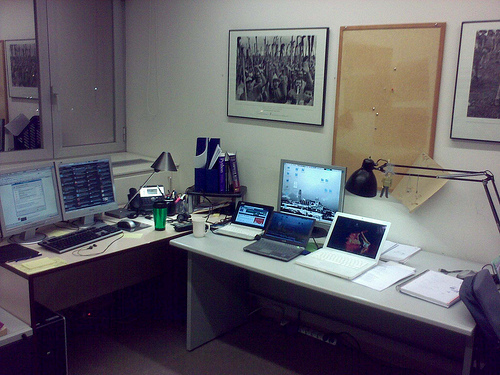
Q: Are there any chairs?
A: No, there are no chairs.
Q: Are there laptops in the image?
A: Yes, there is a laptop.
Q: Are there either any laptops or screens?
A: Yes, there is a laptop.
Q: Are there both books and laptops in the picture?
A: Yes, there are both a laptop and a book.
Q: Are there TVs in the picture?
A: No, there are no tvs.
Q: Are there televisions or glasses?
A: No, there are no televisions or glasses.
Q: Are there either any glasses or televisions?
A: No, there are no televisions or glasses.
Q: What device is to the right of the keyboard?
A: The device is a laptop.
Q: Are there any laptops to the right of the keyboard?
A: Yes, there is a laptop to the right of the keyboard.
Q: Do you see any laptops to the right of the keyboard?
A: Yes, there is a laptop to the right of the keyboard.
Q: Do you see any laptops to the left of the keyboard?
A: No, the laptop is to the right of the keyboard.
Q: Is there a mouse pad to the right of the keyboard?
A: No, there is a laptop to the right of the keyboard.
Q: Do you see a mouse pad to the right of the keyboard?
A: No, there is a laptop to the right of the keyboard.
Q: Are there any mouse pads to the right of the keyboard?
A: No, there is a laptop to the right of the keyboard.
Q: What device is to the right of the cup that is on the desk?
A: The device is a laptop.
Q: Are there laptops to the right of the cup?
A: Yes, there is a laptop to the right of the cup.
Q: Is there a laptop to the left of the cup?
A: No, the laptop is to the right of the cup.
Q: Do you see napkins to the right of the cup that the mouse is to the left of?
A: No, there is a laptop to the right of the cup.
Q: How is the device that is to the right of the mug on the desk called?
A: The device is a laptop.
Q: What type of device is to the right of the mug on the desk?
A: The device is a laptop.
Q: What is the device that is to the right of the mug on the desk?
A: The device is a laptop.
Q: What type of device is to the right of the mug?
A: The device is a laptop.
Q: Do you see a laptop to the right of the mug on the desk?
A: Yes, there is a laptop to the right of the mug.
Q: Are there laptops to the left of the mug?
A: No, the laptop is to the right of the mug.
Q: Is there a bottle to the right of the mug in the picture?
A: No, there is a laptop to the right of the mug.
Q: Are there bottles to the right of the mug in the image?
A: No, there is a laptop to the right of the mug.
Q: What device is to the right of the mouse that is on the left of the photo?
A: The device is a laptop.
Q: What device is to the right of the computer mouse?
A: The device is a laptop.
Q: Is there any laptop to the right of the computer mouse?
A: Yes, there is a laptop to the right of the computer mouse.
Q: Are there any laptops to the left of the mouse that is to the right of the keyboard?
A: No, the laptop is to the right of the mouse.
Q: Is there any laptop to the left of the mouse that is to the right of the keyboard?
A: No, the laptop is to the right of the mouse.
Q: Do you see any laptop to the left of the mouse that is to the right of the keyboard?
A: No, the laptop is to the right of the mouse.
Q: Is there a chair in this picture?
A: No, there are no chairs.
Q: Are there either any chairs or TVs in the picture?
A: No, there are no chairs or tvs.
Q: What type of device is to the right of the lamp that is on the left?
A: The device is a computer monitor.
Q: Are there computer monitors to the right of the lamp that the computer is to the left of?
A: Yes, there is a computer monitor to the right of the lamp.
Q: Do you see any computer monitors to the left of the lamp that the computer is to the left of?
A: No, the computer monitor is to the right of the lamp.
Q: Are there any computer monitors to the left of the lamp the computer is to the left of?
A: No, the computer monitor is to the right of the lamp.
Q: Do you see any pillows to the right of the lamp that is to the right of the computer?
A: No, there is a computer monitor to the right of the lamp.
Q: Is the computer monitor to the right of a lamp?
A: Yes, the computer monitor is to the right of a lamp.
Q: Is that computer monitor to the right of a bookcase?
A: No, the computer monitor is to the right of a lamp.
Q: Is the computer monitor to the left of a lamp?
A: No, the computer monitor is to the right of a lamp.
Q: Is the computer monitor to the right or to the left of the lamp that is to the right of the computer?
A: The computer monitor is to the right of the lamp.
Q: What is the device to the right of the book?
A: The device is a computer monitor.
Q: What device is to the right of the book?
A: The device is a computer monitor.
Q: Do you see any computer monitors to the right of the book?
A: Yes, there is a computer monitor to the right of the book.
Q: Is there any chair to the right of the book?
A: No, there is a computer monitor to the right of the book.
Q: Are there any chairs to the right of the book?
A: No, there is a computer monitor to the right of the book.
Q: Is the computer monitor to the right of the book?
A: Yes, the computer monitor is to the right of the book.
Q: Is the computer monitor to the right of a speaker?
A: No, the computer monitor is to the right of the book.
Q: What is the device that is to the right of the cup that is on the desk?
A: The device is a computer monitor.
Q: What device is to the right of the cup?
A: The device is a computer monitor.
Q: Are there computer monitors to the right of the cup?
A: Yes, there is a computer monitor to the right of the cup.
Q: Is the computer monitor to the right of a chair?
A: No, the computer monitor is to the right of the cup.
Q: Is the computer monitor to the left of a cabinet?
A: No, the computer monitor is to the left of a lamp.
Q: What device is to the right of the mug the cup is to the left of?
A: The device is a computer monitor.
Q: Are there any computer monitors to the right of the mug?
A: Yes, there is a computer monitor to the right of the mug.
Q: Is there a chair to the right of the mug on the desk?
A: No, there is a computer monitor to the right of the mug.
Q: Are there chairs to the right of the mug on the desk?
A: No, there is a computer monitor to the right of the mug.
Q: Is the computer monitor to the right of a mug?
A: Yes, the computer monitor is to the right of a mug.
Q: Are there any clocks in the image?
A: No, there are no clocks.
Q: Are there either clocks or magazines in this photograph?
A: No, there are no clocks or magazines.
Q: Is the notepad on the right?
A: Yes, the notepad is on the right of the image.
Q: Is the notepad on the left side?
A: No, the notepad is on the right of the image.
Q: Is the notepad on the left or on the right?
A: The notepad is on the right of the image.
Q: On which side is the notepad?
A: The notepad is on the right of the image.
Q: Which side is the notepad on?
A: The notepad is on the right of the image.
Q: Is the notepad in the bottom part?
A: Yes, the notepad is in the bottom of the image.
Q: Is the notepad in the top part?
A: No, the notepad is in the bottom of the image.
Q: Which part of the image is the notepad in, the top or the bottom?
A: The notepad is in the bottom of the image.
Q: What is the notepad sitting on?
A: The notepad is sitting on the desk.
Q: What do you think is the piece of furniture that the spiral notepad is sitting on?
A: The piece of furniture is a desk.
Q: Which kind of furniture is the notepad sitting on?
A: The notepad is sitting on the desk.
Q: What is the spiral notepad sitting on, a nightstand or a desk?
A: The notepad is sitting on a desk.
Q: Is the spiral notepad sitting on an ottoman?
A: No, the notepad is sitting on the desk.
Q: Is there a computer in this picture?
A: Yes, there is a computer.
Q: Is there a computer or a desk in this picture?
A: Yes, there is a computer.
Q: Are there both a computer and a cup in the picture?
A: Yes, there are both a computer and a cup.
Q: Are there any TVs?
A: No, there are no tvs.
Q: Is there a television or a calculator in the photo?
A: No, there are no televisions or calculators.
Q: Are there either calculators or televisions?
A: No, there are no televisions or calculators.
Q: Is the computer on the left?
A: Yes, the computer is on the left of the image.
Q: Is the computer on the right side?
A: No, the computer is on the left of the image.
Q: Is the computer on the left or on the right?
A: The computer is on the left of the image.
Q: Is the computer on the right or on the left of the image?
A: The computer is on the left of the image.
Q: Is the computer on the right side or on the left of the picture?
A: The computer is on the left of the image.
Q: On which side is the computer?
A: The computer is on the left of the image.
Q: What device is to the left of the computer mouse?
A: The device is a computer.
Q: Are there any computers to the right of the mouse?
A: No, the computer is to the left of the mouse.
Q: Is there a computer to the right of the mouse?
A: No, the computer is to the left of the mouse.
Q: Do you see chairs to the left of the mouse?
A: No, there is a computer to the left of the mouse.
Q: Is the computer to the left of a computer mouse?
A: Yes, the computer is to the left of a computer mouse.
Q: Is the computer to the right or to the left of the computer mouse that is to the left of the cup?
A: The computer is to the left of the computer mouse.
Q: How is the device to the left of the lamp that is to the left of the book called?
A: The device is a computer.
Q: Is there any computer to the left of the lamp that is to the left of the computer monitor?
A: Yes, there is a computer to the left of the lamp.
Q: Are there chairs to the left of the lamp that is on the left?
A: No, there is a computer to the left of the lamp.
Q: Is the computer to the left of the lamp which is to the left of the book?
A: Yes, the computer is to the left of the lamp.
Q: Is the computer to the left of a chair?
A: No, the computer is to the left of the lamp.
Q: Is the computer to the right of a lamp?
A: No, the computer is to the left of a lamp.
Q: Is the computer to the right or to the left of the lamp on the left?
A: The computer is to the left of the lamp.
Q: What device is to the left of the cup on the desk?
A: The device is a computer.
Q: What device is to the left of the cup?
A: The device is a computer.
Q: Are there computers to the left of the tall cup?
A: Yes, there is a computer to the left of the cup.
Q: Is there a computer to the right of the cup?
A: No, the computer is to the left of the cup.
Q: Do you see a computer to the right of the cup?
A: No, the computer is to the left of the cup.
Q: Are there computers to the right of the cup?
A: No, the computer is to the left of the cup.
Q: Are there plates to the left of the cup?
A: No, there is a computer to the left of the cup.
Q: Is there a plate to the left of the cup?
A: No, there is a computer to the left of the cup.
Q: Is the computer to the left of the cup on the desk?
A: Yes, the computer is to the left of the cup.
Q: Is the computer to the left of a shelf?
A: No, the computer is to the left of the cup.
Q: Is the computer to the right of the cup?
A: No, the computer is to the left of the cup.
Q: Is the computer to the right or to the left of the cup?
A: The computer is to the left of the cup.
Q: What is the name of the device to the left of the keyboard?
A: The device is a computer.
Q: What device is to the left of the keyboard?
A: The device is a computer.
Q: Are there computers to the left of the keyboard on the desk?
A: Yes, there is a computer to the left of the keyboard.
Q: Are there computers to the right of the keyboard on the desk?
A: No, the computer is to the left of the keyboard.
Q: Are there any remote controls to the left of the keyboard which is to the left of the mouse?
A: No, there is a computer to the left of the keyboard.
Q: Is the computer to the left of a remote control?
A: No, the computer is to the left of the keyboard.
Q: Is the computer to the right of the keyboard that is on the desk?
A: No, the computer is to the left of the keyboard.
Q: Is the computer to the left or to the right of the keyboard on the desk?
A: The computer is to the left of the keyboard.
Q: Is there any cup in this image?
A: Yes, there is a cup.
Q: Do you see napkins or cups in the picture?
A: Yes, there is a cup.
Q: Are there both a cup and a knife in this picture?
A: No, there is a cup but no knives.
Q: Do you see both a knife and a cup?
A: No, there is a cup but no knives.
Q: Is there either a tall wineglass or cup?
A: Yes, there is a tall cup.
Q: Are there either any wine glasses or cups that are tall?
A: Yes, the cup is tall.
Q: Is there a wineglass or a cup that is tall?
A: Yes, the cup is tall.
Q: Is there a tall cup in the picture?
A: Yes, there is a tall cup.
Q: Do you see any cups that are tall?
A: Yes, there is a cup that is tall.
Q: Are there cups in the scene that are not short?
A: Yes, there is a tall cup.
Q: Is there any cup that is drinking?
A: Yes, there is a cup that is drinking.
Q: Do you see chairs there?
A: No, there are no chairs.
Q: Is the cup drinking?
A: Yes, the cup is drinking.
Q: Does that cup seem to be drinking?
A: Yes, the cup is drinking.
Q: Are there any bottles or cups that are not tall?
A: No, there is a cup but it is tall.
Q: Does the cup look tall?
A: Yes, the cup is tall.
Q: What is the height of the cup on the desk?
A: The cup is tall.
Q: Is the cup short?
A: No, the cup is tall.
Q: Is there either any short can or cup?
A: No, there is a cup but it is tall.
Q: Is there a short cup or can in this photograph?
A: No, there is a cup but it is tall.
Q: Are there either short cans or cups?
A: No, there is a cup but it is tall.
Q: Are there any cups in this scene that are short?
A: No, there is a cup but it is tall.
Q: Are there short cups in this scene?
A: No, there is a cup but it is tall.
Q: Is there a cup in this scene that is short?
A: No, there is a cup but it is tall.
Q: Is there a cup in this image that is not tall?
A: No, there is a cup but it is tall.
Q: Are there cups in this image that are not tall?
A: No, there is a cup but it is tall.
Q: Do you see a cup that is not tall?
A: No, there is a cup but it is tall.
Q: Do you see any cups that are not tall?
A: No, there is a cup but it is tall.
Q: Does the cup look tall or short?
A: The cup is tall.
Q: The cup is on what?
A: The cup is on the desk.